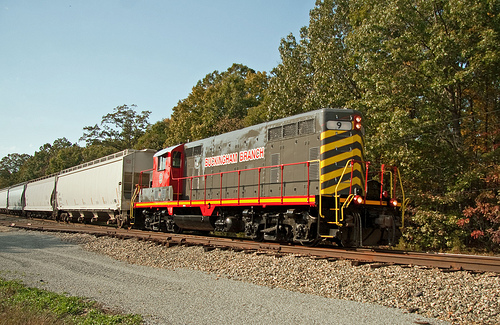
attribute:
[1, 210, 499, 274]
track — rusty, brown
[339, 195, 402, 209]
line — yellow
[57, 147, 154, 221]
car — white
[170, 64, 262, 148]
tree — green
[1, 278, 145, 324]
grass — green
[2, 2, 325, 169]
sky — blue, clear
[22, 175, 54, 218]
traincar — gray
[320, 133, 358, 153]
stripe — yellow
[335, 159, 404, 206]
railings — multi colored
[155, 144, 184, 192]
portion — red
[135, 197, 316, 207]
stripe — yellow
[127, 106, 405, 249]
locomotive — red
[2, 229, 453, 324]
road — gravel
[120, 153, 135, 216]
ladder — white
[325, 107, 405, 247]
front — yellow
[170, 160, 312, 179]
rail — red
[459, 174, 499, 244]
leaves — red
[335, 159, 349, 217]
railing — yellow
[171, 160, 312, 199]
railing — red